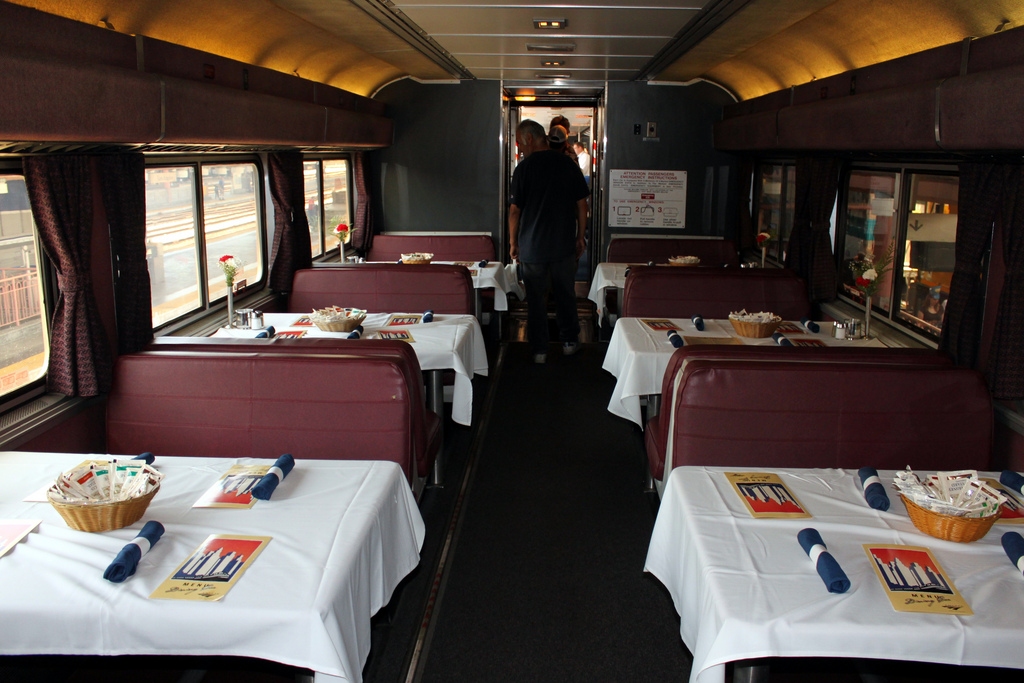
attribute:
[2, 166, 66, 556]
window — train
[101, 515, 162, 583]
blue cloth — blue  